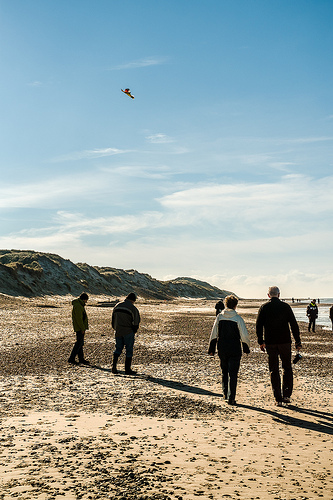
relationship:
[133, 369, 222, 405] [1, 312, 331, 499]
shadow on sand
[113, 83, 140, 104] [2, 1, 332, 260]
object in air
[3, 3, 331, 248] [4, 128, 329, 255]
sky has clouds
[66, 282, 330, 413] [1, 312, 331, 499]
people walking on beach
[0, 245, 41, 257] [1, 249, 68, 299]
plants are on dunes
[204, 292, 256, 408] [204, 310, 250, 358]
woman wears sweater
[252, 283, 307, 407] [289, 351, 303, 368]
man holding camera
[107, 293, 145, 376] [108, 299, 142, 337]
man wearing jacket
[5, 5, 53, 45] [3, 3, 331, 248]
part of sky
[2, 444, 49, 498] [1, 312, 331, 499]
part of ground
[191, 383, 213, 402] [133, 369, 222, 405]
part of shade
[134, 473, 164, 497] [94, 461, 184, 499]
part of stones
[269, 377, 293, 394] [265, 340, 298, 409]
part of trouser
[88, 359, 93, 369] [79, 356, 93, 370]
part of shoe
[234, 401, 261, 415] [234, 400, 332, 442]
edge of shadow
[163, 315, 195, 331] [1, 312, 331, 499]
part of beach